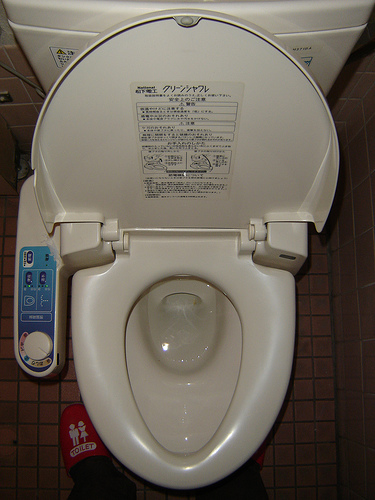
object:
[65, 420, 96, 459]
toilet symbol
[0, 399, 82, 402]
grout line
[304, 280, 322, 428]
line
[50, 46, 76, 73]
label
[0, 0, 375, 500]
toilet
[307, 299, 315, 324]
grout line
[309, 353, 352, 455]
tile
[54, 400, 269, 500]
person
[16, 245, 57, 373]
controls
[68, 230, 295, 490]
seat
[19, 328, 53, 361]
button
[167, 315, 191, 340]
water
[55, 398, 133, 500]
cup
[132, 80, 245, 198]
sticker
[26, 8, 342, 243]
back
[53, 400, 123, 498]
shoe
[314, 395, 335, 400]
grout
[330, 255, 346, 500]
line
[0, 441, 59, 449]
line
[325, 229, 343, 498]
grout line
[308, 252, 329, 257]
grout line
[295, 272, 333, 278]
grout line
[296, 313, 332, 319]
grout line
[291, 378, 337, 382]
grout line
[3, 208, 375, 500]
floor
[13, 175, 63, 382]
arm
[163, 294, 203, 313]
hole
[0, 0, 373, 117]
tank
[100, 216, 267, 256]
hinges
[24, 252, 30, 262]
button